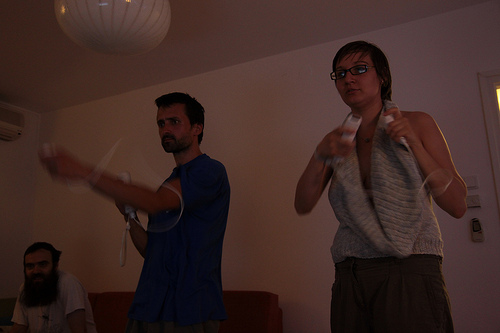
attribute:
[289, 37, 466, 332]
female — young, adult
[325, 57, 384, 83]
glasses — dark rimmed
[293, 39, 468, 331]
woman — a, dark haired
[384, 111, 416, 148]
hand — woman's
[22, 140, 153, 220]
wii controllers — white 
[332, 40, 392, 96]
hair — short, brown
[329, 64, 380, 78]
glasses — Black 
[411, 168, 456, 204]
wire — white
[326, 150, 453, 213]
wires — white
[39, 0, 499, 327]
wall — pink 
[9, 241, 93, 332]
man — sitting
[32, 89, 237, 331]
man — playing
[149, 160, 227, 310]
shirt — black 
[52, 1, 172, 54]
object — round, white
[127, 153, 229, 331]
t-shirt — blue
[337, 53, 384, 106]
face — woman's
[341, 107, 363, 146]
wii remote — white 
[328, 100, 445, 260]
sweater — gray, sleeveless, low cut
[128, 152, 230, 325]
shirt — blue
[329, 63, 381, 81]
glasses — black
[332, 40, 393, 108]
hair — brunette